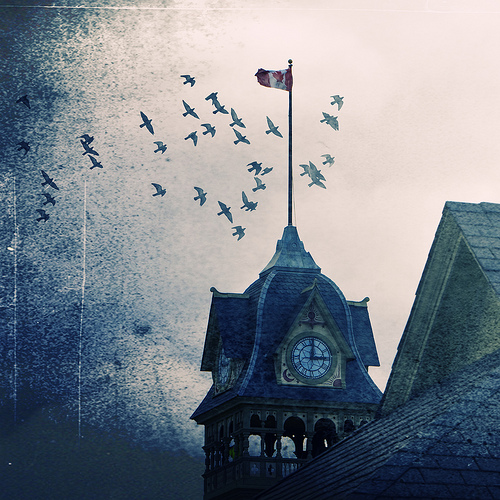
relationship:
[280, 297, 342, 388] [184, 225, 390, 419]
clock on cupola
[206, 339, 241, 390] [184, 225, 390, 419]
clock on cupola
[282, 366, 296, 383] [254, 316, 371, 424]
half moon on clock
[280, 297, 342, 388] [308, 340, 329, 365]
clock says 3 o'clock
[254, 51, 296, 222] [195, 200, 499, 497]
flag pole on top of building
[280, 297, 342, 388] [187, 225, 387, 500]
clock at top of building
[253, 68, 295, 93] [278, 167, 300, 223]
flag on pole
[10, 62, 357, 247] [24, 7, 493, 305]
birds in sky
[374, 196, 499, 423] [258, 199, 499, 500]
roof of building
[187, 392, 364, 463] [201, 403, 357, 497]
windows in viewing area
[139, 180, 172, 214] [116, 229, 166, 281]
black bird in sky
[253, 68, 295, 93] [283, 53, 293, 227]
flag on pole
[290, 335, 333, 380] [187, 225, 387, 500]
clock on building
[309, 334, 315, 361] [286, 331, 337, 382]
hand on clock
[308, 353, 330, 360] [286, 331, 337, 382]
hand on clock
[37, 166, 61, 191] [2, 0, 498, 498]
black bird in sky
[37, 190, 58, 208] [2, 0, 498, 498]
black bird in sky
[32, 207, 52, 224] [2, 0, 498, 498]
black bird in sky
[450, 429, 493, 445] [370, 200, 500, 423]
shingle on roof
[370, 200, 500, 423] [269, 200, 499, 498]
roof of building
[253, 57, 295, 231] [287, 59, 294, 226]
flag on flag pole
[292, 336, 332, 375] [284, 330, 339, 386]
roman numerals on clock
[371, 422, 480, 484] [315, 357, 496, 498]
gray shingles on roof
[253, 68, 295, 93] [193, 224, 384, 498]
flag on clock tower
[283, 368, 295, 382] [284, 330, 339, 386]
half moon on clock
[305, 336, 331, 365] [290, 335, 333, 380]
3 o'clock on clock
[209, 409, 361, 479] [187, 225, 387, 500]
viewing area on building